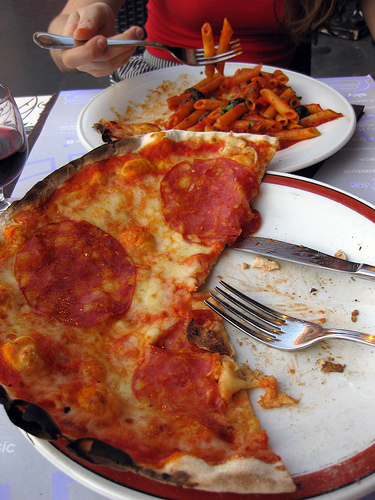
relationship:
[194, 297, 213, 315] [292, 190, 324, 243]
sauce on plate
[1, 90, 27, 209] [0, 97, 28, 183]
glass of wine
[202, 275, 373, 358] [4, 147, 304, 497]
fork by pizza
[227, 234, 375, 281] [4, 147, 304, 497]
knife by pizza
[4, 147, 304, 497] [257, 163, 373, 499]
pizza on plate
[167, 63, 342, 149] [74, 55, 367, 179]
pasta on plate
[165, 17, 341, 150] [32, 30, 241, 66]
pasta on fork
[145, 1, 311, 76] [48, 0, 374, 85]
shirt on woman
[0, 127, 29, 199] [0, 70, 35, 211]
red wine in glass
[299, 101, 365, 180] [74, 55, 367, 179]
napkin under plate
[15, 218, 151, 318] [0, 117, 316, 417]
pepperoni on pizza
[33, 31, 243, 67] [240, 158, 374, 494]
fork on plate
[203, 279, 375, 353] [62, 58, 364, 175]
fork on plate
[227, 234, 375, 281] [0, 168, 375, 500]
knife on plate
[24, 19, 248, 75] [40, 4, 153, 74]
fork in hand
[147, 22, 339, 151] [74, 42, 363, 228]
pasta dish on plate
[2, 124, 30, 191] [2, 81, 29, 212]
red wine in wine glass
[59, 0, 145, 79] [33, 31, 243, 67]
woman's hand holding fork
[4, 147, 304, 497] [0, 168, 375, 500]
pizza on plate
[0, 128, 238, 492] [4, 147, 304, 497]
crust on pizza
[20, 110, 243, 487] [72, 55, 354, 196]
cheese on plate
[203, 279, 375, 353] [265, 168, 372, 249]
fork on plate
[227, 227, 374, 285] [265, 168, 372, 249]
knife on plate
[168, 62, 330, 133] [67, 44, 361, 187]
pasta in bowl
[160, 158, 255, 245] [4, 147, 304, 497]
pepperoni on top of pizza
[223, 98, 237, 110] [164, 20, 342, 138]
spice on top of pasta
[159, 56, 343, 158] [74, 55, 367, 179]
noodles on plate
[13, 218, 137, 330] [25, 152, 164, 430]
pepperoni on pizza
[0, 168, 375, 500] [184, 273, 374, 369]
plate on fork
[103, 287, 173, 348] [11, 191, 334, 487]
cheese on pizza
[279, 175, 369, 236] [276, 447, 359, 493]
plate with rim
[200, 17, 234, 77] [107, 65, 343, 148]
pasta with sauce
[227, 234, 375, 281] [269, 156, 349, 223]
knife on plate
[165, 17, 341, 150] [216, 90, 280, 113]
pasta with tomato sauce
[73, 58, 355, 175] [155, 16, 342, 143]
dish with pasta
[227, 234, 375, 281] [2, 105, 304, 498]
knife used to cut pizza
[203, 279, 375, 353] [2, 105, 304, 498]
fork used to cut pizza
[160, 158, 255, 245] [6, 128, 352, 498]
pepperoni on a pizza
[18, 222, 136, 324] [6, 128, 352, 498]
pepperoni on a pizza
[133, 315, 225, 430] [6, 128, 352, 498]
pepperoni on a pizza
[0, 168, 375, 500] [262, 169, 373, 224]
plate with red trim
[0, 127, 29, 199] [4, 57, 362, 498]
red wine served with meal